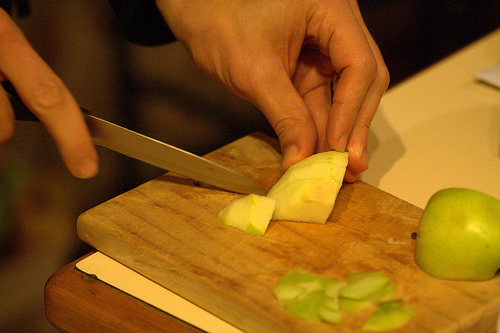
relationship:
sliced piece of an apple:
[217, 192, 278, 236] [412, 186, 499, 280]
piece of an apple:
[217, 192, 278, 236] [412, 186, 499, 280]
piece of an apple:
[269, 151, 349, 223] [412, 186, 499, 280]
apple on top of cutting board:
[219, 150, 499, 282] [76, 131, 500, 332]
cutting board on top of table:
[76, 131, 500, 332] [42, 29, 499, 331]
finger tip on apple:
[325, 125, 349, 150] [269, 151, 349, 223]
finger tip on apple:
[346, 146, 365, 164] [269, 151, 349, 223]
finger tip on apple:
[278, 142, 317, 172] [269, 151, 349, 223]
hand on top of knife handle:
[1, 8, 100, 180] [0, 82, 91, 131]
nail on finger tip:
[76, 155, 101, 178] [59, 151, 102, 181]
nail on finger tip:
[280, 144, 299, 161] [278, 142, 317, 172]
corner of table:
[43, 252, 242, 331] [42, 29, 499, 331]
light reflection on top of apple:
[430, 200, 492, 269] [412, 186, 499, 280]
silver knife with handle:
[88, 115, 267, 195] [0, 82, 91, 131]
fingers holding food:
[280, 126, 369, 183] [269, 151, 349, 223]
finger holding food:
[324, 100, 350, 149] [269, 151, 349, 223]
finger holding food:
[348, 124, 371, 159] [269, 151, 349, 223]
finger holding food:
[276, 68, 318, 172] [269, 151, 349, 223]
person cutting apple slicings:
[0, 0, 392, 184] [217, 191, 274, 234]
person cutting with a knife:
[0, 0, 392, 184] [1, 78, 265, 194]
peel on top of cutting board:
[272, 268, 417, 331] [76, 131, 500, 332]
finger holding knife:
[16, 62, 101, 180] [1, 78, 265, 194]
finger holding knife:
[0, 86, 18, 145] [1, 78, 265, 194]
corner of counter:
[43, 252, 242, 331] [42, 29, 499, 331]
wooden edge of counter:
[45, 265, 201, 332] [42, 29, 499, 331]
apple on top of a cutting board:
[412, 186, 499, 280] [76, 131, 500, 332]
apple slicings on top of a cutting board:
[217, 191, 274, 234] [76, 131, 500, 332]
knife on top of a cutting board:
[1, 78, 265, 194] [76, 131, 500, 332]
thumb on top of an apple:
[276, 68, 318, 172] [269, 151, 349, 223]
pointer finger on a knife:
[16, 62, 101, 180] [1, 78, 265, 194]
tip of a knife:
[210, 162, 269, 195] [1, 78, 265, 194]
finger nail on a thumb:
[280, 144, 299, 161] [257, 83, 319, 176]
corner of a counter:
[43, 252, 242, 331] [42, 29, 499, 331]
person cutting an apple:
[0, 0, 392, 184] [219, 150, 499, 282]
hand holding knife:
[1, 8, 100, 180] [1, 78, 265, 194]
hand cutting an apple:
[1, 8, 100, 180] [219, 150, 499, 282]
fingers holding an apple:
[280, 126, 369, 183] [219, 150, 499, 282]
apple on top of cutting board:
[412, 186, 499, 280] [76, 131, 500, 332]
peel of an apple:
[272, 268, 417, 331] [412, 186, 499, 280]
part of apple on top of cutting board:
[412, 186, 499, 280] [76, 131, 500, 332]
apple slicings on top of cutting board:
[217, 191, 274, 234] [76, 131, 500, 332]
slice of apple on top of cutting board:
[217, 192, 278, 236] [76, 131, 500, 332]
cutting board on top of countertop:
[76, 131, 500, 332] [42, 29, 499, 331]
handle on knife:
[0, 82, 91, 131] [1, 78, 265, 194]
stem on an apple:
[409, 231, 420, 240] [412, 186, 499, 280]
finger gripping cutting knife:
[16, 62, 101, 180] [1, 78, 265, 194]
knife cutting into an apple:
[1, 78, 265, 194] [219, 150, 499, 282]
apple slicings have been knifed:
[217, 150, 351, 237] [1, 78, 265, 194]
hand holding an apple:
[154, 1, 391, 183] [269, 151, 349, 223]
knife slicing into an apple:
[1, 78, 265, 194] [269, 151, 349, 223]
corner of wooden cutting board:
[421, 208, 500, 331] [76, 131, 500, 332]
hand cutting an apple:
[1, 8, 100, 180] [269, 151, 349, 223]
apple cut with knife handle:
[219, 150, 499, 282] [1, 78, 265, 194]